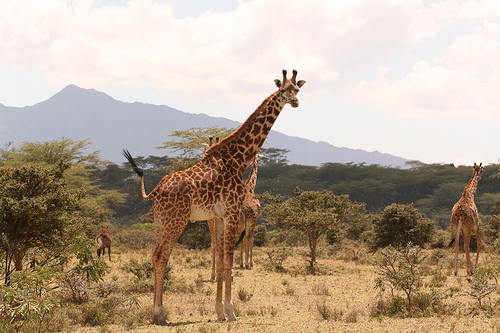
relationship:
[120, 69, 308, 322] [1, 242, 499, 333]
giraffe on plain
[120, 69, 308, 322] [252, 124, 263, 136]
giraffe has spot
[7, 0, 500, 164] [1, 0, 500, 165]
cloud in sky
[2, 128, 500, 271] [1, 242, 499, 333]
trees on plain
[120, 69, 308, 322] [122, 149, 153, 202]
giraffe has tail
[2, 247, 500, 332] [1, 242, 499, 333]
grass on plain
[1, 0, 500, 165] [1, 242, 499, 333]
sky over plain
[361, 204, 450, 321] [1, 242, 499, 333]
bush on plain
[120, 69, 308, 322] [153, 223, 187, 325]
giraffe has leg